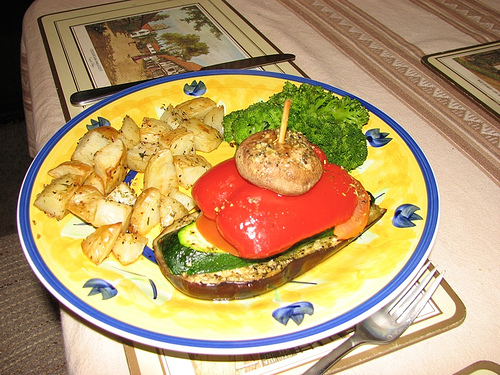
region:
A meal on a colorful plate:
[15, 64, 446, 361]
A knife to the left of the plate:
[64, 48, 301, 111]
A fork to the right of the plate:
[291, 257, 447, 374]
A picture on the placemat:
[41, 0, 326, 118]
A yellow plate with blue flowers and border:
[18, 67, 439, 358]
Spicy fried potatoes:
[33, 94, 230, 265]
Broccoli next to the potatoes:
[218, 80, 378, 170]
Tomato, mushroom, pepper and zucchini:
[144, 94, 386, 303]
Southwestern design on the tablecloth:
[274, 1, 499, 188]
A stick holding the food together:
[276, 99, 295, 146]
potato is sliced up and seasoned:
[91, 222, 126, 276]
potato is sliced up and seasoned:
[134, 190, 166, 233]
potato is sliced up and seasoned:
[144, 154, 178, 197]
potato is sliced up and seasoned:
[41, 182, 68, 212]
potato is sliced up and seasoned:
[104, 147, 128, 192]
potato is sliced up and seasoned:
[180, 115, 222, 155]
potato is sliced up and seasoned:
[172, 77, 217, 119]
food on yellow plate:
[59, 75, 408, 336]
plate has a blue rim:
[20, 53, 425, 350]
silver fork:
[298, 274, 453, 374]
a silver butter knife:
[27, 32, 325, 118]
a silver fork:
[293, 252, 461, 372]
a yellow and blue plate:
[15, 67, 450, 368]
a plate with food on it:
[38, 89, 388, 362]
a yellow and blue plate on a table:
[18, 93, 474, 371]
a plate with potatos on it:
[23, 96, 243, 266]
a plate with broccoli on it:
[143, 59, 433, 202]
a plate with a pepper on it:
[92, 60, 407, 323]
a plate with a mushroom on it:
[147, 103, 339, 274]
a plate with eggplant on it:
[124, 146, 375, 307]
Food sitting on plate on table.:
[33, 57, 378, 302]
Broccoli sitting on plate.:
[225, 82, 371, 166]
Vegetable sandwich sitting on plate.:
[153, 128, 391, 298]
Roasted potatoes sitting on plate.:
[38, 115, 151, 265]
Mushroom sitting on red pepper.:
[235, 126, 327, 196]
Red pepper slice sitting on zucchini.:
[191, 159, 362, 256]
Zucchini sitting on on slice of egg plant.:
[160, 223, 246, 276]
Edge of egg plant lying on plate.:
[189, 262, 352, 307]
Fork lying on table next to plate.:
[301, 256, 447, 373]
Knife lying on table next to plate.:
[59, 47, 308, 108]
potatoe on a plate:
[81, 216, 126, 259]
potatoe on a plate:
[136, 188, 162, 223]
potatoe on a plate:
[85, 201, 130, 226]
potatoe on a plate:
[45, 182, 73, 213]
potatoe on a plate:
[136, 150, 171, 176]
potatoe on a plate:
[88, 142, 124, 183]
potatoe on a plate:
[166, 122, 194, 147]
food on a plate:
[241, 133, 361, 284]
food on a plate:
[307, 85, 352, 140]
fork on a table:
[64, 83, 100, 110]